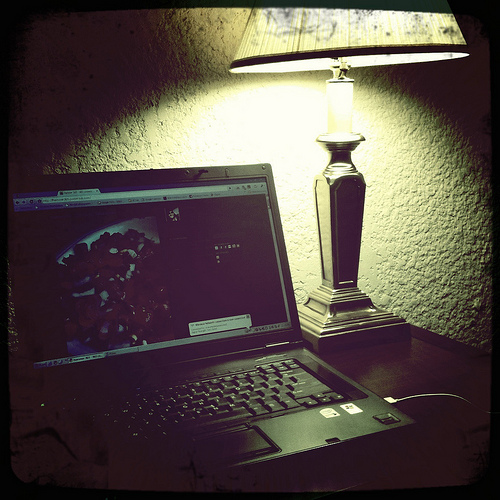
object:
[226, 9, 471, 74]
lamp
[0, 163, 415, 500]
laptop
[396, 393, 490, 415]
cord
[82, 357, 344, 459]
keyboard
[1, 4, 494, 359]
wall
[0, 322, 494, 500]
table